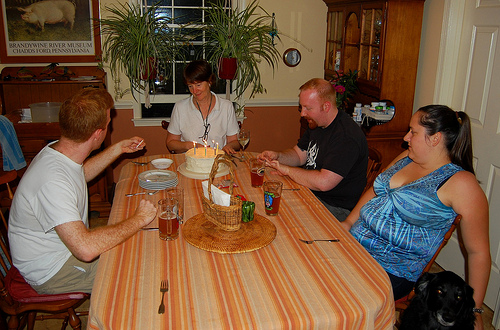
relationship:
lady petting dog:
[338, 104, 492, 319] [395, 267, 494, 329]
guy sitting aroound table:
[4, 89, 157, 296] [88, 151, 405, 328]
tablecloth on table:
[108, 241, 460, 328] [207, 256, 313, 309]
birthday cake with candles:
[177, 147, 230, 179] [179, 132, 252, 180]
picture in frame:
[0, 6, 107, 66] [1, 2, 101, 80]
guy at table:
[4, 89, 157, 296] [117, 138, 370, 323]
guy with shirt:
[259, 78, 368, 220] [307, 129, 360, 194]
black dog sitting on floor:
[400, 270, 478, 329] [435, 253, 456, 278]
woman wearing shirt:
[166, 56, 243, 156] [164, 89, 239, 149]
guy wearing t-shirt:
[4, 89, 157, 296] [6, 138, 91, 286]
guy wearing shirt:
[259, 78, 368, 220] [286, 121, 372, 213]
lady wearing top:
[338, 104, 492, 319] [370, 160, 443, 270]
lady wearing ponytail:
[338, 104, 492, 319] [453, 106, 482, 190]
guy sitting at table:
[259, 78, 368, 220] [88, 151, 405, 328]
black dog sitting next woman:
[400, 270, 478, 329] [330, 97, 497, 315]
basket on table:
[197, 163, 240, 229] [88, 151, 405, 328]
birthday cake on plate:
[177, 147, 230, 179] [188, 172, 191, 178]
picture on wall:
[0, 6, 101, 64] [105, 1, 128, 21]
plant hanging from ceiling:
[192, 2, 280, 98] [283, 0, 312, 18]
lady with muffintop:
[338, 82, 494, 319] [362, 200, 395, 242]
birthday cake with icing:
[177, 147, 230, 179] [184, 162, 211, 174]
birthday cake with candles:
[177, 147, 230, 179] [189, 139, 219, 154]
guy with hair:
[4, 89, 157, 296] [312, 87, 336, 97]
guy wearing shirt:
[259, 78, 368, 220] [305, 130, 366, 197]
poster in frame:
[8, 4, 98, 52] [42, 55, 111, 63]